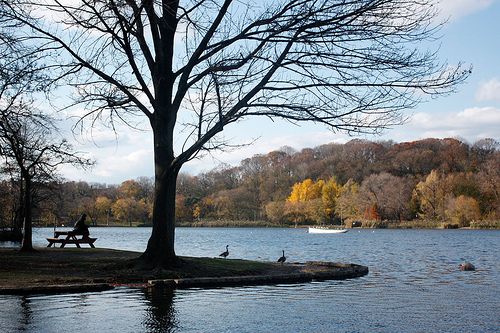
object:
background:
[0, 133, 498, 230]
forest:
[0, 134, 500, 228]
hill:
[296, 173, 496, 224]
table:
[45, 231, 97, 249]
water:
[368, 231, 498, 259]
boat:
[309, 227, 350, 233]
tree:
[0, 0, 475, 264]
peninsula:
[184, 256, 369, 285]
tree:
[285, 178, 323, 204]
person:
[72, 214, 93, 240]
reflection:
[138, 287, 181, 333]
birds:
[219, 244, 287, 266]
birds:
[358, 230, 376, 233]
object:
[461, 260, 476, 271]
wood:
[60, 240, 76, 245]